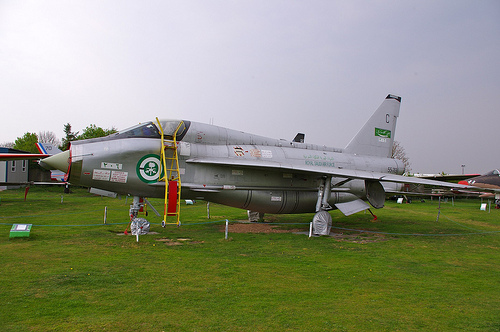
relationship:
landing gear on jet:
[312, 208, 336, 238] [36, 91, 479, 236]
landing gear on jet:
[243, 208, 267, 224] [36, 91, 479, 236]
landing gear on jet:
[128, 194, 153, 238] [36, 91, 479, 236]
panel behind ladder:
[165, 177, 176, 214] [155, 115, 184, 227]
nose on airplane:
[39, 145, 69, 175] [36, 94, 481, 237]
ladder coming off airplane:
[159, 132, 181, 226] [36, 94, 481, 237]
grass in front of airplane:
[0, 185, 499, 330] [33, 92, 498, 238]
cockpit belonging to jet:
[124, 116, 192, 144] [36, 91, 479, 236]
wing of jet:
[183, 157, 483, 192] [14, 65, 486, 239]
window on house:
[20, 156, 27, 172] [2, 151, 45, 192]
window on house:
[10, 161, 15, 171] [2, 151, 45, 192]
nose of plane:
[39, 145, 75, 174] [33, 92, 474, 275]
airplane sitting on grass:
[46, 105, 481, 230] [8, 193, 484, 297]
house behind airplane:
[1, 146, 34, 193] [33, 92, 498, 238]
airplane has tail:
[36, 94, 481, 237] [345, 92, 405, 157]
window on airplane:
[116, 119, 163, 140] [33, 92, 498, 238]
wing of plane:
[183, 157, 483, 192] [34, 96, 493, 247]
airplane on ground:
[36, 94, 481, 237] [14, 186, 483, 330]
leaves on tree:
[14, 132, 39, 151] [3, 128, 53, 195]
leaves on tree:
[14, 132, 39, 151] [54, 122, 117, 178]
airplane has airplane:
[36, 94, 481, 237] [36, 94, 481, 237]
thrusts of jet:
[381, 155, 405, 202] [31, 82, 481, 249]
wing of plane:
[183, 157, 489, 192] [47, 56, 469, 260]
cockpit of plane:
[124, 116, 192, 142] [11, 23, 487, 267]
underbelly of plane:
[194, 184, 334, 219] [31, 73, 498, 240]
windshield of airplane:
[147, 118, 185, 135] [41, 93, 475, 233]